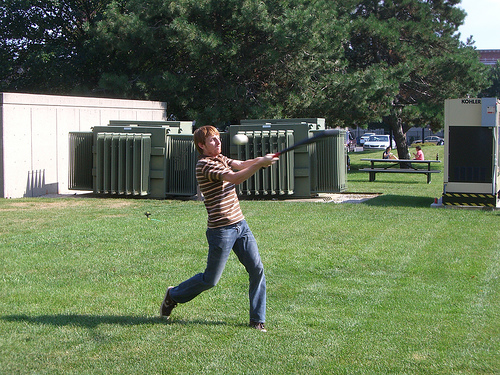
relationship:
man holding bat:
[187, 116, 225, 175] [267, 118, 348, 165]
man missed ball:
[187, 116, 225, 175] [228, 130, 271, 160]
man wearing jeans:
[187, 116, 225, 175] [184, 223, 275, 326]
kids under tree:
[375, 140, 433, 161] [309, 25, 441, 125]